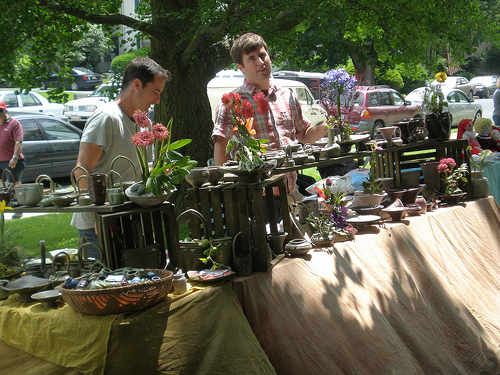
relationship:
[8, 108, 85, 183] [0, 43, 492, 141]
car in parking lot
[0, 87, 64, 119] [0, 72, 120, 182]
car in parking lot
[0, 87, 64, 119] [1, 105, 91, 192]
car in parking lot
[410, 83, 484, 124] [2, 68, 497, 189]
car in parking lot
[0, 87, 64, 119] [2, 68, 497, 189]
car in parking lot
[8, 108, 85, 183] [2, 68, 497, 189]
car in parking lot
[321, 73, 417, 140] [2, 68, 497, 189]
car in parking lot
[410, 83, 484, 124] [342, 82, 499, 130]
car in parking lot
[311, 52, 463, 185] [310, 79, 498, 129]
car in parking lot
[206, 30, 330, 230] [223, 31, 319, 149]
man with shirt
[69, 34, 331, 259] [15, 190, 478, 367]
men standing behind table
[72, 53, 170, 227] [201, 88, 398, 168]
man standing behind flowers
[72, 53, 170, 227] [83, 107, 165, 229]
man wearing shirt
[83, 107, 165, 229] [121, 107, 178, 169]
shirt behind flowers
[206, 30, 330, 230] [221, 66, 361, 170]
man standing behind flowers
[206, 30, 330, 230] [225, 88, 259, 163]
man behind flowers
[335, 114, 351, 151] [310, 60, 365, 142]
stem of flowers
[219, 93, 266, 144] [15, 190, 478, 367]
flower on table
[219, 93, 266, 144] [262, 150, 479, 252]
flower on table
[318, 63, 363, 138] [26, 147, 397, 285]
flower on table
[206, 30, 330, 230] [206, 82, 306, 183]
man wearing shirt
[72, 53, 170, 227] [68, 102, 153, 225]
man wearing shirt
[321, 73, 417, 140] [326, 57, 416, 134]
car in a parking